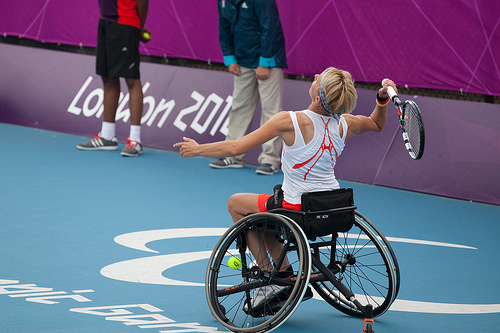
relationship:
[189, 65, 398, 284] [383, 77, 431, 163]
woman holding racket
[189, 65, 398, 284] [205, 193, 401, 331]
woman in wheelchair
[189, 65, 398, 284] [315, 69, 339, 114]
player wearing headband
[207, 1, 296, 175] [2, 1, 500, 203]
umpire in background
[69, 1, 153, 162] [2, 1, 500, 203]
ball runner in background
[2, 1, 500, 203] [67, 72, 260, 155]
background has london 2010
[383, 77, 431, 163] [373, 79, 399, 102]
racket in hand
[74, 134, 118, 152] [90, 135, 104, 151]
shoe has stripes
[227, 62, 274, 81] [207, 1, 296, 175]
hands of person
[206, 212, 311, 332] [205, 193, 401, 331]
wheel of wheelchair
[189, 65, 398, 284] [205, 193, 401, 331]
player on wheelchair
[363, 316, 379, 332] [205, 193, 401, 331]
wheel on wheelchair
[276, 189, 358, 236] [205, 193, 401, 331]
seat on wheelchair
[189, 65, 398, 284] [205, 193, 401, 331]
player in wheelchair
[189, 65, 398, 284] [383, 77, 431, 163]
player holding racket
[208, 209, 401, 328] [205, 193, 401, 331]
wheels on wheelchair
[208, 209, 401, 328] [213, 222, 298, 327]
wheels has spokes